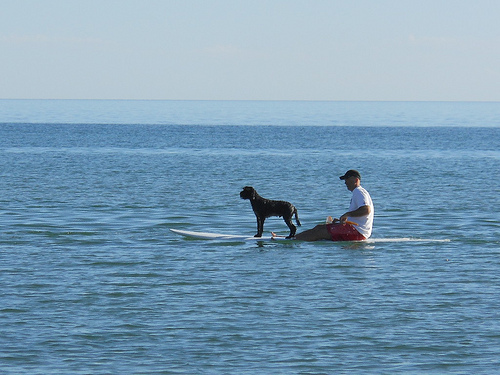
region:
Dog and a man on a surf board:
[161, 163, 458, 251]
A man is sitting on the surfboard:
[260, 166, 376, 242]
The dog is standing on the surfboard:
[233, 183, 304, 241]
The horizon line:
[2, 90, 499, 107]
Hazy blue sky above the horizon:
[3, 0, 498, 105]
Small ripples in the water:
[2, 119, 499, 370]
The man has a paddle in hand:
[329, 214, 359, 229]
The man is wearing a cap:
[336, 168, 362, 182]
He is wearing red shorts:
[324, 218, 369, 244]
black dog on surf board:
[227, 181, 293, 238]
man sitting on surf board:
[303, 142, 371, 253]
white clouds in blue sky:
[252, 36, 323, 81]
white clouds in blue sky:
[190, 32, 219, 57]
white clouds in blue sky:
[87, 24, 155, 75]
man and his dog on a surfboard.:
[165, 162, 392, 253]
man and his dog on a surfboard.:
[162, 161, 384, 261]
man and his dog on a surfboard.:
[165, 163, 386, 253]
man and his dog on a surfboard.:
[166, 162, 411, 247]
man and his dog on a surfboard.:
[165, 162, 417, 247]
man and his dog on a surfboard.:
[166, 162, 407, 247]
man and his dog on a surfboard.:
[167, 167, 422, 254]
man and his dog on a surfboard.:
[162, 161, 413, 251]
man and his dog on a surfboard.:
[161, 161, 389, 251]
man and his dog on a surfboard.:
[157, 165, 394, 251]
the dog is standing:
[233, 185, 302, 235]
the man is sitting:
[317, 159, 382, 238]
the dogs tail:
[293, 210, 306, 226]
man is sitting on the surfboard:
[305, 163, 395, 243]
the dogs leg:
[251, 215, 267, 237]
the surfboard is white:
[168, 230, 253, 242]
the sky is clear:
[181, 11, 370, 86]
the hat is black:
[334, 169, 363, 179]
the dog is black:
[239, 185, 310, 238]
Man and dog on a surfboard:
[166, 157, 458, 250]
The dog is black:
[235, 181, 306, 241]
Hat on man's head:
[336, 163, 364, 192]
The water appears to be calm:
[2, 120, 499, 373]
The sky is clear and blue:
[2, 2, 498, 103]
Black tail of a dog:
[287, 201, 307, 229]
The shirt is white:
[342, 183, 377, 242]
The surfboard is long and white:
[166, 222, 455, 249]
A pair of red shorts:
[322, 219, 369, 245]